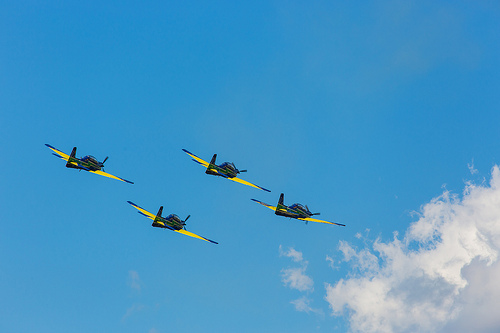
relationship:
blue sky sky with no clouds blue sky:
[125, 31, 231, 98] [0, 0, 499, 333]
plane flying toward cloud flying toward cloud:
[250, 192, 347, 227] [253, 150, 416, 304]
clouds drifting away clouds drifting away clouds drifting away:
[277, 250, 318, 313] [266, 236, 347, 316]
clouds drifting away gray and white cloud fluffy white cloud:
[277, 250, 318, 313] [323, 159, 500, 332]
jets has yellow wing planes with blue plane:
[45, 143, 132, 184] [250, 192, 347, 227]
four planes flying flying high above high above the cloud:
[39, 89, 376, 261] [203, 85, 427, 269]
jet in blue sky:
[183, 148, 270, 193] [0, 0, 499, 333]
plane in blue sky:
[246, 190, 349, 229] [0, 0, 499, 333]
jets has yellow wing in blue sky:
[45, 143, 132, 184] [0, 0, 499, 333]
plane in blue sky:
[115, 188, 226, 251] [0, 0, 499, 333]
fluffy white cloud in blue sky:
[372, 193, 468, 304] [0, 0, 499, 333]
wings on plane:
[125, 200, 225, 248] [129, 193, 220, 249]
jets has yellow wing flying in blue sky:
[45, 143, 132, 184] [0, 0, 499, 333]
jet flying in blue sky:
[183, 148, 270, 193] [0, 0, 499, 333]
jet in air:
[183, 148, 270, 193] [25, 87, 397, 294]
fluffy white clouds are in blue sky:
[372, 193, 468, 304] [0, 0, 499, 333]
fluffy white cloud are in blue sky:
[323, 159, 500, 332] [0, 0, 499, 333]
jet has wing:
[183, 148, 270, 193] [52, 135, 342, 248]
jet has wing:
[183, 148, 270, 193] [54, 130, 352, 240]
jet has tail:
[188, 146, 266, 186] [198, 152, 220, 186]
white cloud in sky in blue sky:
[372, 193, 468, 304] [0, 0, 499, 333]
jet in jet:
[183, 148, 270, 193] [183, 148, 270, 193]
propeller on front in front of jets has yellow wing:
[90, 149, 128, 174] [45, 143, 132, 184]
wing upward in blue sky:
[174, 138, 207, 168] [0, 0, 499, 333]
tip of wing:
[252, 180, 280, 203] [228, 169, 277, 198]